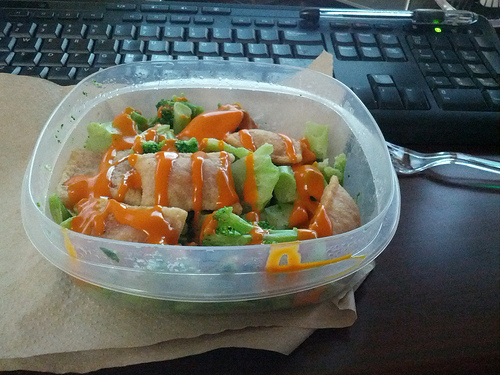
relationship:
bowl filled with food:
[20, 37, 404, 315] [70, 104, 363, 249]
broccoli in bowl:
[61, 97, 346, 250] [20, 37, 404, 315]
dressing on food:
[68, 107, 341, 237] [70, 104, 363, 249]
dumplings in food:
[90, 144, 357, 249] [70, 104, 363, 249]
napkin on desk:
[1, 41, 374, 369] [13, 141, 499, 373]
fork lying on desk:
[375, 132, 500, 177] [13, 141, 499, 373]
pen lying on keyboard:
[299, 6, 475, 29] [2, 1, 499, 146]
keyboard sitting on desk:
[2, 1, 499, 146] [13, 141, 499, 373]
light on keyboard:
[433, 26, 443, 34] [2, 1, 499, 146]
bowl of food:
[20, 37, 404, 315] [70, 104, 363, 249]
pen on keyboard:
[299, 6, 475, 29] [2, 1, 499, 146]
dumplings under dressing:
[90, 144, 357, 249] [68, 107, 341, 237]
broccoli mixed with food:
[61, 97, 346, 250] [70, 104, 363, 249]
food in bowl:
[70, 104, 363, 249] [20, 37, 404, 315]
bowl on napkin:
[20, 37, 404, 315] [1, 41, 374, 369]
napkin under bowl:
[1, 41, 374, 369] [20, 37, 404, 315]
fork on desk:
[375, 132, 500, 177] [13, 141, 499, 373]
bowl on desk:
[20, 37, 404, 315] [13, 141, 499, 373]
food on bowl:
[70, 104, 363, 249] [20, 37, 404, 315]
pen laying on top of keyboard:
[299, 6, 475, 29] [2, 1, 499, 146]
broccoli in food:
[61, 97, 346, 250] [70, 104, 363, 249]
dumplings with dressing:
[90, 144, 357, 249] [68, 107, 341, 237]